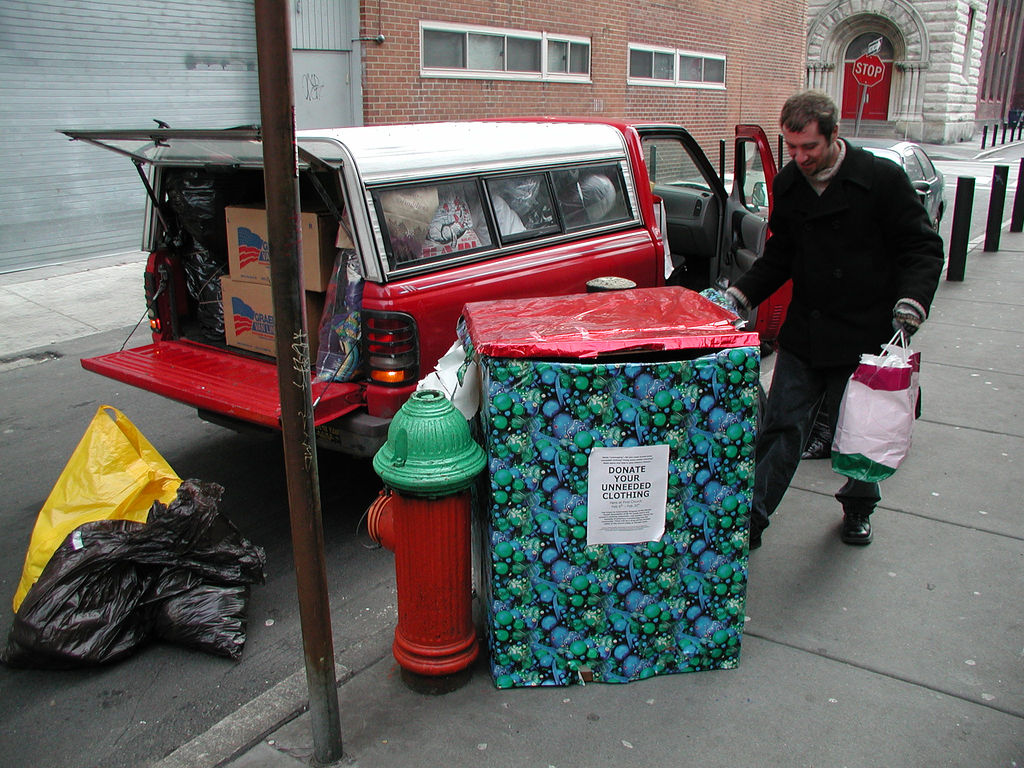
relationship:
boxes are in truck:
[220, 204, 341, 366] [57, 118, 781, 458]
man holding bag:
[724, 91, 946, 553] [828, 329, 924, 480]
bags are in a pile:
[13, 481, 268, 670] [7, 405, 269, 673]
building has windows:
[361, 0, 806, 186] [421, 22, 730, 86]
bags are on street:
[13, 481, 268, 670] [0, 141, 1023, 767]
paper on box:
[588, 442, 670, 546] [459, 283, 760, 690]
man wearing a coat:
[724, 91, 946, 553] [726, 141, 947, 366]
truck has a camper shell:
[57, 118, 781, 458] [55, 120, 645, 284]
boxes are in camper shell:
[220, 204, 341, 366] [55, 120, 645, 284]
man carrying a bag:
[724, 91, 946, 553] [828, 329, 924, 480]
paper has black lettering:
[588, 442, 670, 546] [597, 455, 657, 535]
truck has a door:
[57, 118, 781, 458] [720, 123, 779, 284]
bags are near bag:
[13, 481, 268, 670] [11, 404, 184, 615]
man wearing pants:
[724, 91, 946, 553] [750, 345, 883, 551]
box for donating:
[459, 283, 760, 690] [607, 464, 648, 476]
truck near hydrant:
[57, 118, 781, 458] [363, 391, 491, 696]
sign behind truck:
[851, 55, 889, 135] [57, 118, 781, 458]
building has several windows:
[361, 0, 806, 186] [421, 22, 730, 86]